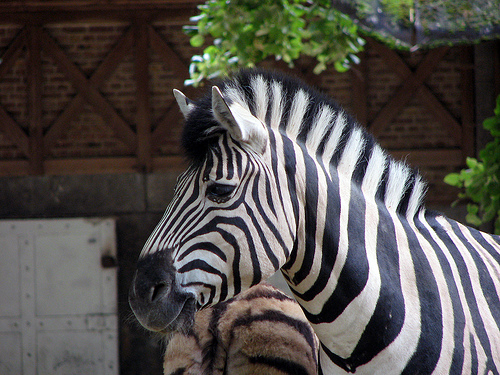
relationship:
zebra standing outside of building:
[109, 66, 499, 373] [6, 7, 493, 367]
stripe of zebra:
[269, 141, 500, 375] [228, 110, 418, 340]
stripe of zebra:
[396, 208, 441, 373] [228, 110, 418, 340]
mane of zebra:
[172, 74, 434, 221] [73, 72, 475, 373]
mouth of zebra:
[137, 301, 194, 338] [109, 66, 499, 373]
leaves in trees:
[181, 0, 497, 230] [188, 0, 498, 221]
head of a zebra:
[130, 83, 302, 335] [109, 66, 499, 373]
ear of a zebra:
[212, 72, 265, 144] [109, 66, 499, 373]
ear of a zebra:
[172, 87, 206, 132] [109, 66, 499, 373]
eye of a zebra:
[204, 184, 239, 199] [175, 76, 469, 346]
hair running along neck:
[181, 67, 429, 218] [268, 127, 408, 340]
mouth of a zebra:
[137, 301, 194, 338] [114, 41, 460, 373]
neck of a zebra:
[310, 157, 398, 352] [109, 66, 499, 373]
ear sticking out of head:
[186, 72, 264, 144] [132, 72, 325, 357]